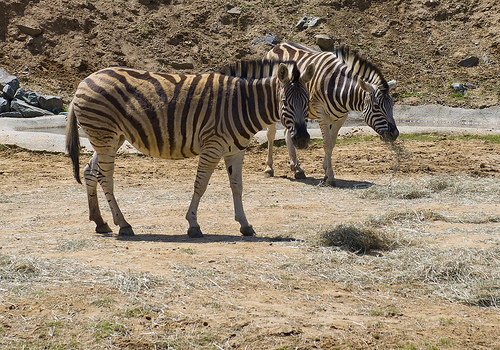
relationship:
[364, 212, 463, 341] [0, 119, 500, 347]
grass on ground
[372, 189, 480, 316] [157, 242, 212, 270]
grass on ground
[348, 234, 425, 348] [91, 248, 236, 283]
grass on ground